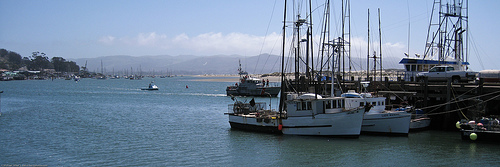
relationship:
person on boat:
[137, 75, 161, 95] [138, 84, 176, 108]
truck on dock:
[413, 60, 466, 88] [365, 69, 445, 114]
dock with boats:
[291, 62, 430, 109] [224, 81, 418, 139]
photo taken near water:
[11, 6, 473, 153] [17, 87, 420, 156]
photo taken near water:
[11, 6, 473, 153] [26, 69, 455, 150]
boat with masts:
[275, 23, 355, 138] [286, 34, 315, 85]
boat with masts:
[337, 13, 415, 130] [341, 28, 376, 83]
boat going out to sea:
[143, 77, 160, 97] [160, 67, 204, 88]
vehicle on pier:
[415, 60, 474, 83] [333, 80, 483, 89]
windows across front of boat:
[294, 97, 342, 116] [229, 100, 364, 138]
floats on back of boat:
[464, 115, 481, 126] [452, 118, 484, 144]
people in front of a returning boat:
[260, 76, 270, 89] [223, 75, 276, 95]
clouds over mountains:
[111, 28, 390, 58] [99, 57, 371, 77]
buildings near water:
[5, 70, 71, 83] [25, 80, 289, 150]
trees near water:
[29, 55, 86, 66] [25, 80, 289, 150]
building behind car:
[399, 55, 457, 77] [413, 64, 471, 81]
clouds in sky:
[129, 26, 257, 54] [33, 5, 247, 36]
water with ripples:
[54, 105, 173, 152] [112, 115, 142, 140]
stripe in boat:
[285, 120, 335, 136] [278, 84, 368, 142]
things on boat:
[455, 119, 476, 140] [455, 114, 498, 138]